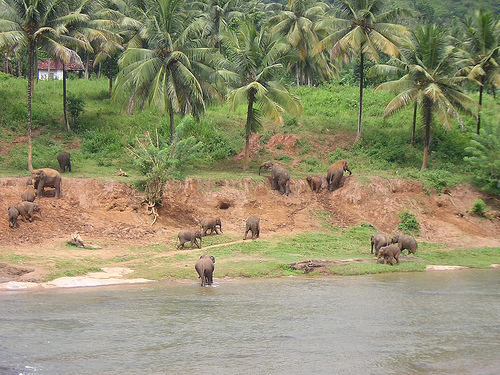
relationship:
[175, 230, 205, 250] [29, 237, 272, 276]
elephant walking along path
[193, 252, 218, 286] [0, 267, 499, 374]
elephant in water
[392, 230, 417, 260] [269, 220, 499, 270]
elephant standing in grass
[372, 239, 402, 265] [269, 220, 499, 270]
elephant standing in grass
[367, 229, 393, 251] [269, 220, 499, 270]
elephant standing in grass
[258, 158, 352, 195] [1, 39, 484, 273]
two elephants walking up hill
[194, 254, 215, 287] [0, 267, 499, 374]
elephant standing in water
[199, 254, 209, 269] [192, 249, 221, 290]
back of elephant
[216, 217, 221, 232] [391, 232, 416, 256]
head on elephant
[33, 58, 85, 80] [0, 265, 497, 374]
house by lake